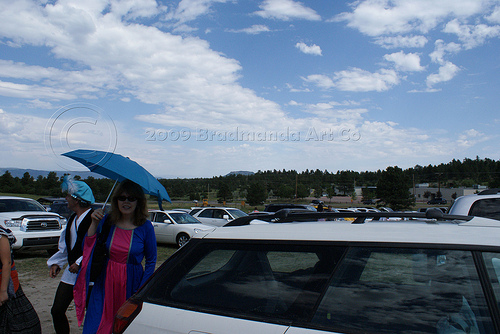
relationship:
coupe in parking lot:
[150, 208, 212, 245] [4, 190, 499, 331]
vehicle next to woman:
[108, 208, 499, 333] [77, 178, 157, 333]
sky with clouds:
[2, 2, 498, 161] [2, 0, 499, 184]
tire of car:
[175, 231, 191, 247] [145, 206, 215, 248]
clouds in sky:
[2, 0, 499, 184] [2, 2, 498, 161]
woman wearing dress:
[77, 178, 157, 333] [75, 215, 156, 332]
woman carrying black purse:
[84, 173, 155, 331] [91, 223, 110, 285]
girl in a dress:
[75, 192, 144, 334] [88, 257, 122, 334]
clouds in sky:
[7, 17, 477, 154] [1, 83, 496, 167]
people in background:
[186, 186, 473, 232] [9, 49, 482, 166]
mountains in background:
[241, 157, 289, 189] [12, 105, 498, 176]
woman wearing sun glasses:
[68, 175, 163, 331] [83, 189, 157, 241]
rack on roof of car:
[177, 192, 450, 232] [196, 210, 489, 325]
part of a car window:
[137, 234, 273, 326] [154, 214, 169, 224]